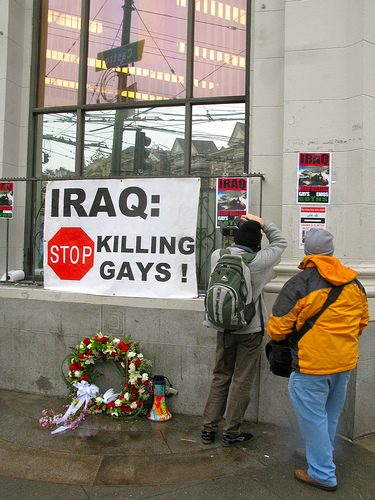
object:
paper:
[297, 151, 331, 204]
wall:
[275, 1, 375, 219]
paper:
[299, 206, 327, 249]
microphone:
[146, 375, 178, 423]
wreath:
[67, 332, 152, 419]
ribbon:
[50, 379, 99, 435]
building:
[1, 1, 375, 441]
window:
[28, 0, 248, 288]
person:
[266, 227, 370, 492]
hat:
[304, 227, 335, 256]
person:
[200, 214, 286, 449]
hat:
[234, 220, 263, 251]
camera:
[220, 215, 246, 236]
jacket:
[266, 254, 369, 375]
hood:
[297, 255, 358, 287]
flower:
[83, 338, 90, 345]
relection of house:
[41, 102, 245, 177]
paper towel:
[0, 270, 25, 282]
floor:
[1, 387, 375, 499]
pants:
[287, 370, 351, 487]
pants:
[201, 331, 263, 438]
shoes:
[295, 465, 338, 492]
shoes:
[222, 431, 255, 447]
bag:
[205, 249, 259, 330]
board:
[44, 177, 201, 297]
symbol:
[48, 227, 95, 280]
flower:
[114, 399, 122, 407]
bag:
[264, 284, 341, 379]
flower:
[134, 359, 142, 366]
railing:
[1, 172, 263, 181]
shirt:
[203, 221, 289, 335]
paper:
[216, 177, 249, 229]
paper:
[0, 180, 13, 220]